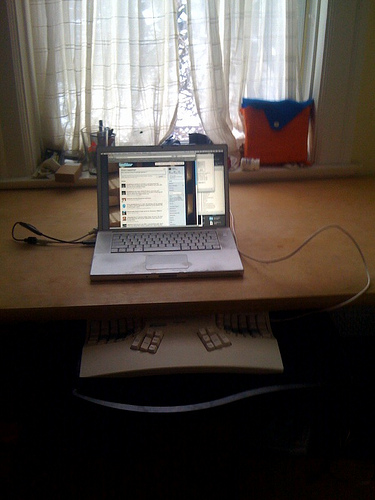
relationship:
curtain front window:
[17, 0, 319, 180] [7, 1, 327, 147]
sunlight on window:
[62, 43, 250, 125] [7, 1, 334, 172]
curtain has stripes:
[17, 0, 319, 180] [41, 53, 310, 74]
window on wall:
[57, 2, 290, 141] [330, 1, 370, 162]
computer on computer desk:
[85, 133, 246, 277] [2, 176, 375, 321]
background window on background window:
[13, 0, 332, 170] [13, 0, 332, 170]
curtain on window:
[17, 0, 319, 180] [22, 2, 298, 147]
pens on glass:
[91, 114, 117, 150] [80, 125, 103, 158]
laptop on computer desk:
[74, 134, 270, 308] [2, 176, 375, 321]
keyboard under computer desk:
[78, 319, 283, 376] [2, 176, 375, 321]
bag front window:
[239, 96, 314, 166] [20, 2, 317, 155]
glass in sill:
[72, 117, 114, 171] [32, 116, 301, 168]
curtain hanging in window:
[17, 0, 319, 180] [5, 2, 366, 171]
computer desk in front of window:
[2, 176, 372, 320] [7, 1, 334, 172]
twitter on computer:
[117, 164, 187, 224] [87, 153, 268, 274]